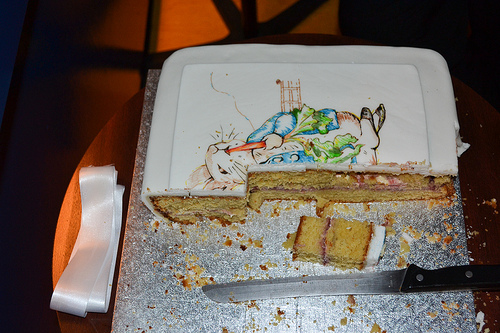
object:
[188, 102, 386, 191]
bunny rabbit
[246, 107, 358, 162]
coat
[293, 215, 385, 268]
slice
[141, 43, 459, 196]
tray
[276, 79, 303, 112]
fence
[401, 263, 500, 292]
handle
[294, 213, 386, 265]
cake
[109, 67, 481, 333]
sheet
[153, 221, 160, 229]
crumb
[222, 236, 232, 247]
crumb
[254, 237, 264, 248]
crumb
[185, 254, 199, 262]
crumb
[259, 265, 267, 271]
crumb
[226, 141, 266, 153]
carrot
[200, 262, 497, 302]
knife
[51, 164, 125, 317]
ribbon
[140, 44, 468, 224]
cake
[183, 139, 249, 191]
head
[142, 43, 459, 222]
frosting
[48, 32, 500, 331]
table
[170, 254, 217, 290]
crumbs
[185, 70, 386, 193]
drawing